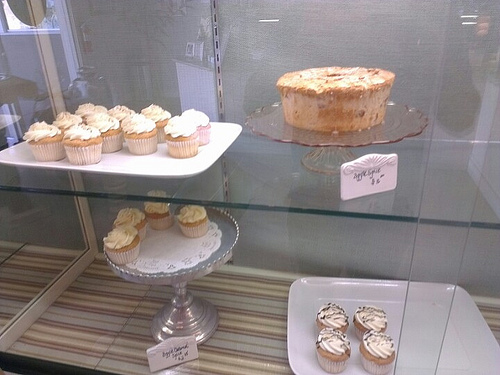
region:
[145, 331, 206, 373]
a white sale sign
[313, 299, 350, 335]
a cupcake on the plate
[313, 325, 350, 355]
frosting on the cupcake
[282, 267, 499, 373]
a large white plate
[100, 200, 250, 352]
a metal platter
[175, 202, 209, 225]
yellow frosting on the cupcake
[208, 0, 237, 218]
a metal beam on the wall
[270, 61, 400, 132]
a brown cake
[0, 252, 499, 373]
striped wallpaper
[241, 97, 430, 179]
a glass platter on the shelf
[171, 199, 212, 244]
a delicious cake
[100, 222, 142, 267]
a delicious cake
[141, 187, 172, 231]
a delicious cake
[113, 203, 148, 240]
a delicious cake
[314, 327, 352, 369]
a delicious cake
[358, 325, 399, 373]
a delicious cake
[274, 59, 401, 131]
a delicious cake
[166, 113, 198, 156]
a delicious cake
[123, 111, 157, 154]
a delicious cake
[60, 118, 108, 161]
a delicious cake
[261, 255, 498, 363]
The plate is white.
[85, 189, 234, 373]
Cupcake tower is silver.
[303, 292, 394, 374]
Four cupcakes on white plate.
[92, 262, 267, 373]
The table has a stripped pattern.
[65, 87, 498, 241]
The shelf is made with glass.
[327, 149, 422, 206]
The tags are white.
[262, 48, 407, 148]
Only one bunt cake.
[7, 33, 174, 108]
Reflections in the glass.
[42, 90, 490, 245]
The shelf is clear.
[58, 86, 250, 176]
10 cupcakes with white frosting.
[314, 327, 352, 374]
a cupcake on the white plate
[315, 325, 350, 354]
white frosting on the cupcake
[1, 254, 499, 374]
striped wall paper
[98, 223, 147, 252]
yellow frosting on the cupcake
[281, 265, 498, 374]
a white plate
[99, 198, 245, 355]
a large metal platter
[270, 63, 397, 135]
a brown cake on the tray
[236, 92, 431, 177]
a glass tray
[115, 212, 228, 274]
a white doily on the platter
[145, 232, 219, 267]
the doilee is white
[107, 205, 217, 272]
four cupcakes on doilee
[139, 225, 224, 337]
the doilee on stand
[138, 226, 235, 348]
doilee stand is silver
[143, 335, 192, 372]
the signs are white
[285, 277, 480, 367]
the plate is white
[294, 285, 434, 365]
four cupcakes on bottom plate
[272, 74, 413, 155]
the cake is brown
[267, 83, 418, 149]
cake stand is glass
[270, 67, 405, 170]
cake is on the stand